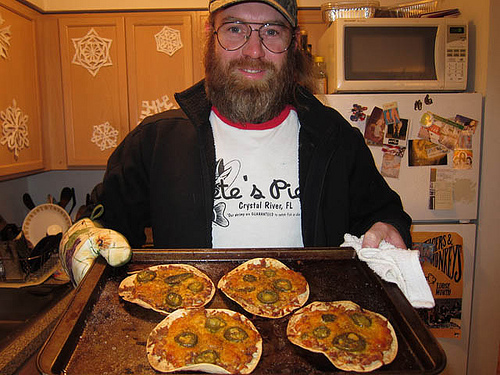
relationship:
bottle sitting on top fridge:
[312, 52, 327, 95] [327, 92, 483, 375]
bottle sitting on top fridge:
[298, 25, 312, 89] [327, 92, 483, 375]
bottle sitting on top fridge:
[305, 42, 314, 66] [327, 92, 483, 375]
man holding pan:
[58, 2, 413, 287] [35, 246, 449, 375]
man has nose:
[58, 0, 412, 289] [243, 35, 262, 57]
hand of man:
[59, 226, 125, 280] [58, 0, 412, 289]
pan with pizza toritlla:
[35, 246, 449, 375] [115, 259, 211, 315]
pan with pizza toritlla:
[35, 246, 449, 375] [218, 252, 301, 327]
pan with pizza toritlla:
[35, 246, 449, 375] [144, 309, 265, 366]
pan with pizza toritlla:
[35, 246, 449, 375] [297, 299, 397, 371]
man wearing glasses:
[58, 0, 412, 289] [214, 17, 294, 54]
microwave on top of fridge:
[317, 18, 468, 95] [327, 92, 483, 375]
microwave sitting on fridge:
[332, 16, 469, 91] [327, 92, 483, 375]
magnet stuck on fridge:
[377, 99, 401, 126] [327, 92, 483, 375]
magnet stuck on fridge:
[412, 100, 423, 113] [327, 92, 483, 375]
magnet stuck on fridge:
[420, 93, 433, 105] [327, 92, 483, 375]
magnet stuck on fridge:
[417, 107, 436, 130] [327, 92, 483, 375]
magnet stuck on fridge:
[449, 144, 474, 170] [327, 92, 483, 375]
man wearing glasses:
[58, 2, 413, 287] [209, 18, 296, 52]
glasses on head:
[210, 8, 310, 56] [196, 5, 328, 115]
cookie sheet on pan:
[117, 257, 397, 375] [26, 238, 446, 372]